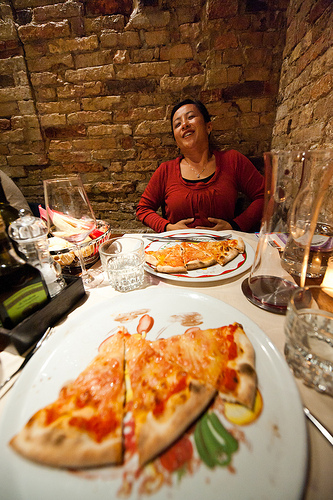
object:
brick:
[94, 179, 132, 193]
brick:
[224, 69, 271, 78]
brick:
[206, 67, 264, 77]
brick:
[160, 73, 208, 87]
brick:
[242, 96, 269, 110]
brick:
[131, 48, 159, 61]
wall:
[114, 14, 234, 101]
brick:
[134, 119, 173, 132]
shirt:
[132, 148, 263, 230]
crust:
[135, 382, 222, 458]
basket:
[47, 220, 112, 273]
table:
[1, 231, 332, 498]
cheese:
[37, 325, 223, 421]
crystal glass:
[97, 233, 149, 299]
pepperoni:
[162, 433, 192, 468]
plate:
[0, 284, 307, 496]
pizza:
[151, 237, 247, 271]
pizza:
[34, 318, 261, 472]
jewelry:
[173, 161, 215, 180]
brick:
[296, 30, 325, 71]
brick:
[269, 120, 291, 133]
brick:
[47, 33, 100, 54]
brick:
[128, 60, 171, 76]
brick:
[214, 29, 241, 49]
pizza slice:
[200, 236, 239, 263]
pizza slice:
[161, 241, 204, 274]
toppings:
[213, 243, 230, 250]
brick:
[221, 76, 269, 106]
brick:
[288, 32, 327, 75]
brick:
[90, 142, 137, 164]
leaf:
[162, 405, 233, 451]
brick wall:
[2, 0, 332, 229]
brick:
[2, 1, 284, 187]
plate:
[139, 226, 254, 283]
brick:
[60, 63, 118, 80]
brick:
[78, 96, 124, 108]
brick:
[93, 147, 138, 160]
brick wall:
[275, 10, 332, 143]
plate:
[131, 223, 261, 291]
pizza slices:
[148, 232, 239, 274]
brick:
[99, 30, 142, 48]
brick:
[0, 85, 33, 101]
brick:
[35, 100, 61, 113]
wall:
[32, 0, 155, 176]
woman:
[132, 95, 279, 235]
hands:
[158, 212, 194, 232]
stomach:
[185, 215, 213, 226]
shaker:
[7, 208, 65, 293]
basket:
[0, 274, 87, 352]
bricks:
[65, 39, 140, 160]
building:
[1, 0, 331, 234]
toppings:
[72, 374, 199, 416]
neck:
[178, 148, 216, 179]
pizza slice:
[7, 328, 124, 469]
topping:
[64, 409, 119, 441]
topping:
[70, 394, 88, 409]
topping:
[69, 331, 125, 400]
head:
[169, 97, 214, 150]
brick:
[290, 121, 322, 146]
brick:
[66, 109, 113, 124]